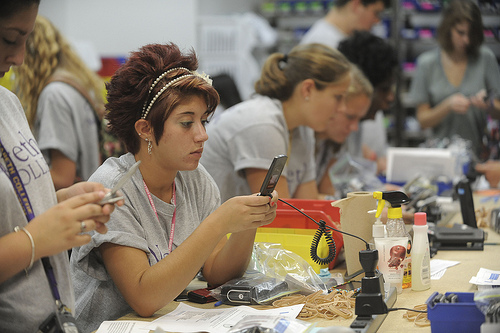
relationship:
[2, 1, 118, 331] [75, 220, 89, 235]
girl wearing ring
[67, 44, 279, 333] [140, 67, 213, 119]
girl wearing head band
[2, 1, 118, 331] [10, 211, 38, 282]
girl wearing bracelet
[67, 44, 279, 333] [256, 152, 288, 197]
girl looking phone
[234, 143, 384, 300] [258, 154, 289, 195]
phone cord connected to phone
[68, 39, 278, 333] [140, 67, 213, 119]
woman wearing a head band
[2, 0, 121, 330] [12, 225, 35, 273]
woman wearing bracelet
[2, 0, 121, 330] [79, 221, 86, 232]
woman wearing ring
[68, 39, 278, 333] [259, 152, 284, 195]
woman looking at cell phone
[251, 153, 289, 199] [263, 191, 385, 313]
phone plugged into charger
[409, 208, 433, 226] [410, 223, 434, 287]
pink cap on clear bottle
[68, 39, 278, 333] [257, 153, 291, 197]
woman using cell phone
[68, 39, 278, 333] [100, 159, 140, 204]
woman using cell phone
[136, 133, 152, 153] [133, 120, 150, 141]
three earrings in ear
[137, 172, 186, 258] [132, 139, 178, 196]
lanyard on neck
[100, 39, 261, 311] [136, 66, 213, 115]
woman wearing head band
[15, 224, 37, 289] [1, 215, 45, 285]
bracelet on wrist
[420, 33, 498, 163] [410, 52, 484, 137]
woman in shirt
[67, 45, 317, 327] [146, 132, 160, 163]
girl has earring